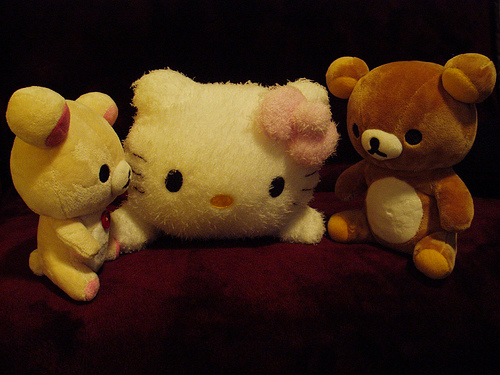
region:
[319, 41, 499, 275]
The teddy bear is brown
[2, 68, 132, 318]
The teddy bear is tan colored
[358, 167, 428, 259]
The teddy bear's belly is white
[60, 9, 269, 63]
The background is black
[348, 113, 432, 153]
Teddy bear's eyes are black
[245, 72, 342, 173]
Stuffed animal is wearing a bow tie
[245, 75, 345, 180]
The bow tie is light pink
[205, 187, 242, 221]
Stuffed animal's nose is yellow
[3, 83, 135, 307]
Side view of a teddy bear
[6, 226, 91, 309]
Teddy bear is casting a shadow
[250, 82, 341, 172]
hello kitty has standard fluffy baby pink bow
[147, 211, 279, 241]
hello kitty has standard invisible mouth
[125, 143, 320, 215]
hello kitty has three cheek whiskers on either side of her face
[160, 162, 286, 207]
hello kitty has two vertically oval black eyes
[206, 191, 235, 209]
hello kitty has one horizontally oval pink nose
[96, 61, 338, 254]
hello kitty is made from fluffy terrycloth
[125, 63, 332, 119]
hello kitty has two lumpy round ears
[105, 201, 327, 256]
hello kitty has two little round feet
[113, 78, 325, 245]
hello kitty has a horizontally oval, almost round head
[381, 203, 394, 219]
brown teddy bear has a dent that resembles a navel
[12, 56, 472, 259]
Three stuffed animals on chair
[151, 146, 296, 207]
Black eyes of stuffed animal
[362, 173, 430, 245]
beige belly of bear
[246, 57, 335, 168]
Pink bow in hair of kitty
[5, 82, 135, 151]
Two pink ears on animal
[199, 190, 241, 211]
Pink nose on middle toy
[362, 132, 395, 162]
Little black nose on brown bear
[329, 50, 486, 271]
On brown bear on the right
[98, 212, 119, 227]
Red button on shirt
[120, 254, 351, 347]
Red chair with toys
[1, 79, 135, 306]
The bear on the left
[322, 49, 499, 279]
The brown bear on the right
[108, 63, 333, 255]
The cat in the middle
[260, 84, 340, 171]
The pink bow on the cat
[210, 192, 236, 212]
The pink nose on the cat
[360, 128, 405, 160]
The nose of the dark brown bear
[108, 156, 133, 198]
The nose of the tan bear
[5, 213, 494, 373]
The blanket the stuffed animals are on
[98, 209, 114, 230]
the red circle on the left bear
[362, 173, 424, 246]
The white stomach of the bear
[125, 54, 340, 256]
Hello Kitty stuffed animal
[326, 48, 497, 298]
Brown stuffed teddy bear with black eyes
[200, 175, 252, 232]
Yellow nose on Hello Kitty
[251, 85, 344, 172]
Pink bow on Hello Kitty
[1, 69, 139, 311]
Yellow stuffed rabbit with a red heart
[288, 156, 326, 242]
Black whiskers on Hello Kitty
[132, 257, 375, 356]
Burgundy cushion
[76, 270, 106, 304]
Pink and yellow paw on rabbit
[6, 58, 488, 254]
Three stuffed animals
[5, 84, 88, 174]
Pink and yellow ear on rabbit